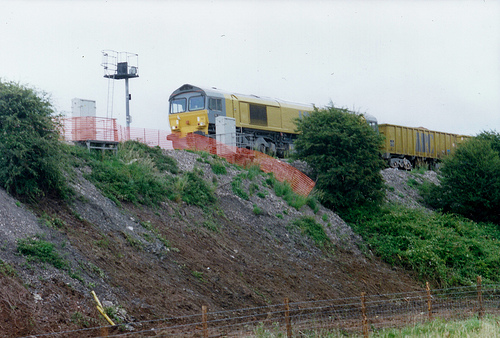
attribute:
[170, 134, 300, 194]
fence — orange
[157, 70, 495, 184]
train — yellow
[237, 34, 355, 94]
sky — grey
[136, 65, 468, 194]
train — long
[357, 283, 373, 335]
post — wooden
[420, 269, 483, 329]
post — wooden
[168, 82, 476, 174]
train. — grain, yellow, visable.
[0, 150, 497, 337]
dirt — dark, brown